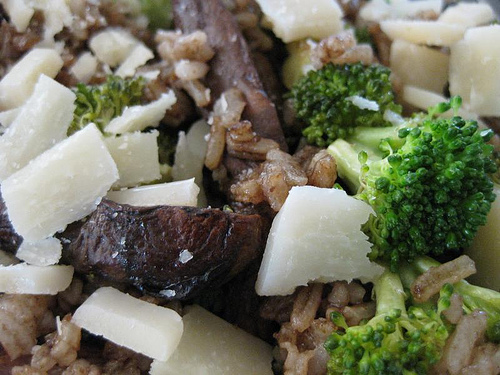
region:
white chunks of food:
[30, 52, 422, 352]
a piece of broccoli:
[283, 72, 498, 266]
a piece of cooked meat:
[35, 193, 249, 309]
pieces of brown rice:
[147, 27, 309, 229]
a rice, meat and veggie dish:
[5, 23, 480, 307]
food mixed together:
[17, 22, 478, 350]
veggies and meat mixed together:
[45, 44, 496, 340]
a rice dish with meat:
[4, 20, 493, 369]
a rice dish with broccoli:
[10, 5, 491, 227]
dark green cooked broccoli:
[290, 110, 487, 287]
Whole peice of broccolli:
[326, 108, 497, 259]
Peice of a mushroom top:
[102, 201, 250, 298]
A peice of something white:
[278, 179, 380, 296]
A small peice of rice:
[404, 260, 479, 298]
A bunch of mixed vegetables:
[26, 43, 487, 257]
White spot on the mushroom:
[178, 251, 194, 263]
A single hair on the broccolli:
[328, 308, 344, 330]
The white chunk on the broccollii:
[350, 92, 378, 110]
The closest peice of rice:
[285, 340, 295, 372]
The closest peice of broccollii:
[326, 258, 499, 372]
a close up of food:
[21, 15, 487, 358]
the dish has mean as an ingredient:
[66, 163, 273, 322]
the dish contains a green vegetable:
[323, 96, 497, 266]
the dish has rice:
[158, 28, 286, 212]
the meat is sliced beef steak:
[43, 159, 281, 314]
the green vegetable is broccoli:
[328, 83, 486, 298]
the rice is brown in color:
[138, 31, 291, 206]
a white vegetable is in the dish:
[252, 163, 397, 314]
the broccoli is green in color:
[315, 88, 492, 268]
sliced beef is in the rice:
[49, 156, 261, 313]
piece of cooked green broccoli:
[369, 109, 492, 253]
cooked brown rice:
[283, 292, 334, 339]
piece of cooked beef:
[89, 194, 264, 305]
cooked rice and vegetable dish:
[105, 30, 396, 297]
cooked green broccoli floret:
[286, 54, 401, 142]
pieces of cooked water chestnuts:
[15, 48, 120, 218]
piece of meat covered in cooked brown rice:
[165, 7, 295, 177]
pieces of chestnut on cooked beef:
[150, 235, 200, 300]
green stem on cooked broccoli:
[319, 136, 357, 176]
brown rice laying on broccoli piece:
[406, 246, 493, 373]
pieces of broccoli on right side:
[261, 49, 497, 373]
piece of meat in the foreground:
[68, 181, 255, 281]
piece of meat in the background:
[158, 4, 301, 146]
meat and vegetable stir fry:
[2, 9, 483, 374]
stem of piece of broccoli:
[326, 117, 386, 179]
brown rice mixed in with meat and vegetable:
[8, 12, 498, 365]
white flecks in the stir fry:
[7, 1, 498, 373]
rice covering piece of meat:
[154, 6, 306, 204]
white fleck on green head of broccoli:
[334, 85, 380, 114]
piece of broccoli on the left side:
[63, 66, 149, 130]